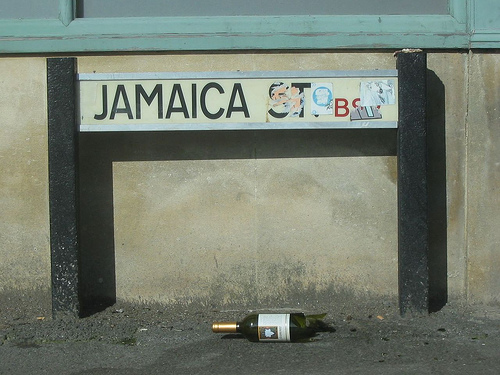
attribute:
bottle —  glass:
[215, 290, 329, 350]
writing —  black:
[100, 87, 252, 110]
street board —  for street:
[35, 50, 445, 312]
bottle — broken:
[208, 308, 310, 342]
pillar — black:
[397, 77, 461, 304]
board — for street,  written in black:
[87, 73, 373, 128]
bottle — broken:
[208, 313, 308, 339]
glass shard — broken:
[291, 307, 335, 341]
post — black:
[40, 54, 82, 316]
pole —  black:
[393, 49, 432, 317]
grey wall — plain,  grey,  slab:
[111, 142, 397, 317]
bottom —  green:
[291, 312, 308, 340]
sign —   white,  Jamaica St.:
[73, 42, 482, 220]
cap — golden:
[209, 317, 239, 337]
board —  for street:
[49, 49, 494, 170]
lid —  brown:
[211, 322, 218, 332]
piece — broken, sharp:
[305, 310, 328, 320]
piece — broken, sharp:
[305, 315, 335, 333]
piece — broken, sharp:
[304, 319, 319, 334]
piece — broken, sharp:
[301, 330, 320, 340]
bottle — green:
[210, 310, 337, 342]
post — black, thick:
[44, 55, 83, 320]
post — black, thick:
[395, 46, 431, 316]